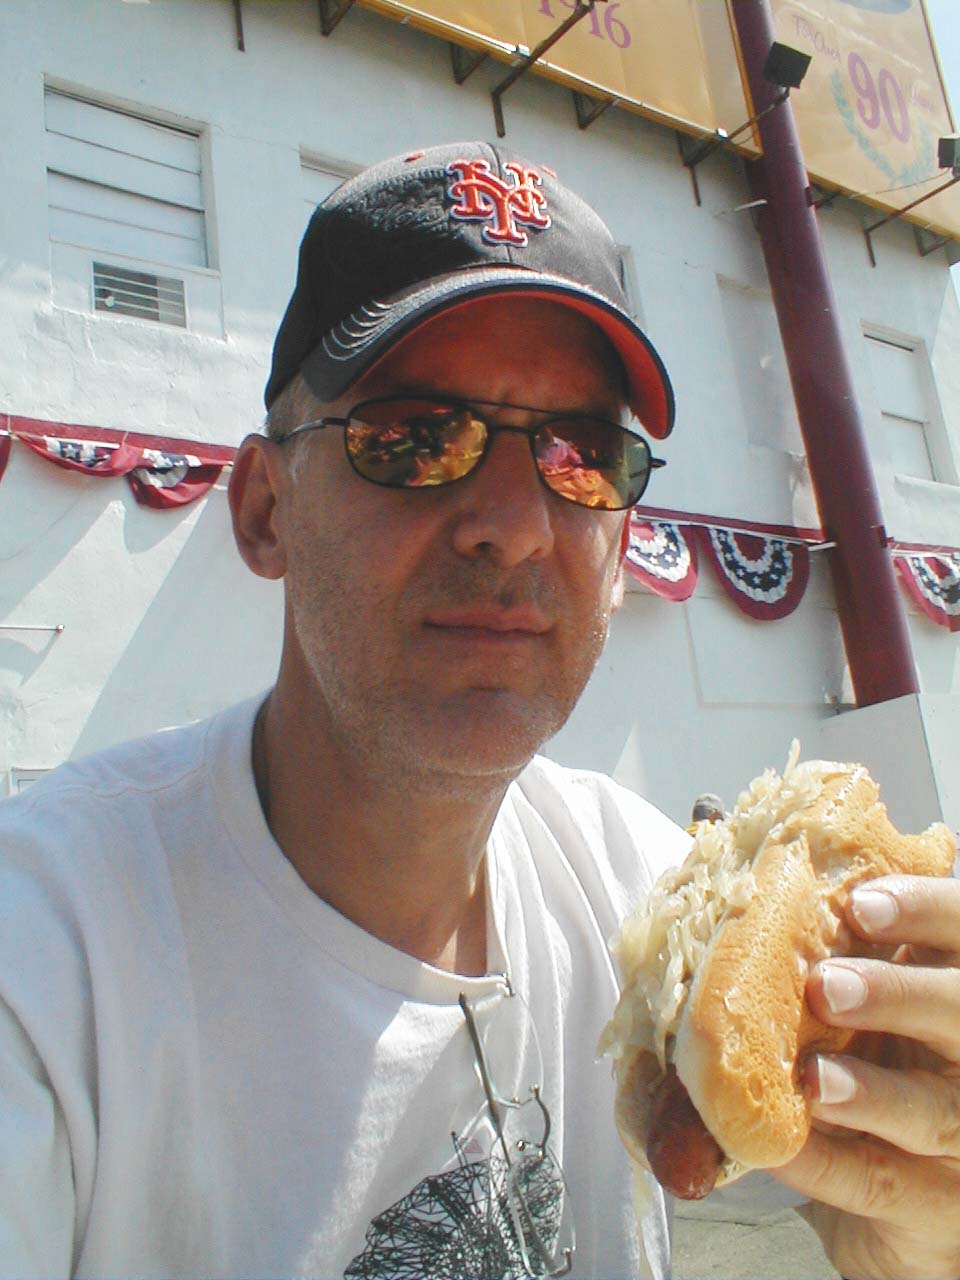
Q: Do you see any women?
A: No, there are no women.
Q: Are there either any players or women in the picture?
A: No, there are no women or players.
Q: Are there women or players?
A: No, there are no women or players.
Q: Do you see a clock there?
A: No, there are no clocks.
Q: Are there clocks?
A: No, there are no clocks.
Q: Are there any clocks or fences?
A: No, there are no clocks or fences.